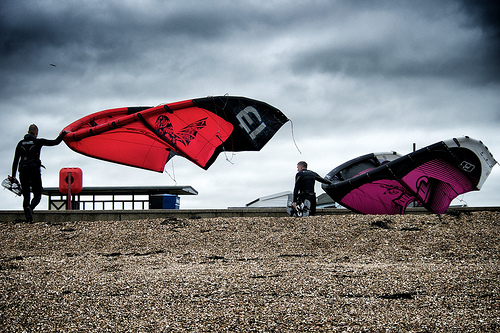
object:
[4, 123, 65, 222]
man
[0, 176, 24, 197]
packet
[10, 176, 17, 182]
hand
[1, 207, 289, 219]
pavement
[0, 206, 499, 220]
tan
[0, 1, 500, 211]
skies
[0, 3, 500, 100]
clouds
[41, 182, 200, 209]
bench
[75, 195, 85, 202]
partition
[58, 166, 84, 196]
container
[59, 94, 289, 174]
fabric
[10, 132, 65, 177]
shirt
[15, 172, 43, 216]
pants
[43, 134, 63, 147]
sleeve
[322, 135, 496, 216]
object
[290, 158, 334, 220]
person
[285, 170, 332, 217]
outfit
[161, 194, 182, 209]
box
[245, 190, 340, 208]
building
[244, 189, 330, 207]
roof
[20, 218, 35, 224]
shoes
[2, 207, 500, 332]
on ground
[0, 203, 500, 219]
platform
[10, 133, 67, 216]
uniform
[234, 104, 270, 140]
design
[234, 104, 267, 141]
letters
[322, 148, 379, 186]
trim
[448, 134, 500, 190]
tips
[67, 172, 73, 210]
post